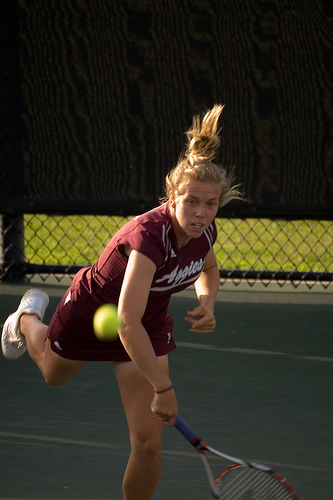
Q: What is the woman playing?
A: Tennis.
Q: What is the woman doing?
A: Swinging.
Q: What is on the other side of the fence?
A: Grass.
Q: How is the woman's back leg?
A: Lifted.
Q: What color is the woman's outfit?
A: Burgundy.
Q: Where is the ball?
A: In air.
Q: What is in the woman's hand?
A: Racquet.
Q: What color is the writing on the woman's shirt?
A: White.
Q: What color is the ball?
A: Yellow.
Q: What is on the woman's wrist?
A: Band.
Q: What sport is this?
A: Tennis.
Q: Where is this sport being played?
A: Tennis court.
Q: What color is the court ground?
A: Green.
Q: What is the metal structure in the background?
A: Fence.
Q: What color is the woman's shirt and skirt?
A: Maroon and white.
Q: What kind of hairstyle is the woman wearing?
A: Bun.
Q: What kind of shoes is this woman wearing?
A: Sneakers.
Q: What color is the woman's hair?
A: Blonde.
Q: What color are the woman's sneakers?
A: White.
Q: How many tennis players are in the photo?
A: One.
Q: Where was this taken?
A: Tennis court.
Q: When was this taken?
A: During a tennis match.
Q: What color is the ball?
A: Yellow.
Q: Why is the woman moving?
A: To hit the ball.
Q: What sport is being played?
A: Tennis.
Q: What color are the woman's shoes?
A: White.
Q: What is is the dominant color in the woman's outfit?
A: Burgundy.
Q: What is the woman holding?
A: A tennis racket.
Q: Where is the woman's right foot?
A: In the air.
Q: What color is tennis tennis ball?
A: Green.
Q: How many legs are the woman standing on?
A: One.